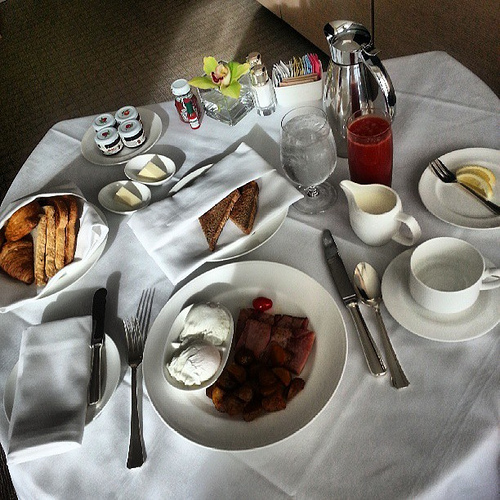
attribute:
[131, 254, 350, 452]
plate — white, round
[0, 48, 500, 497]
table — covered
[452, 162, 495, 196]
lemons — cut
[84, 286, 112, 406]
knife — silver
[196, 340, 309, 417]
potatoes — hashbrowns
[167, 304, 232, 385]
eggs — poached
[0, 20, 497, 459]
meal — fancy, breakfast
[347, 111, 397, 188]
glass — tall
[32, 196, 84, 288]
toast — sliced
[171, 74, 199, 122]
bottle — small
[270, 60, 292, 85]
sugar — collected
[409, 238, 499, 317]
cup — empty, white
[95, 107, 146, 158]
jellies — individual, jarred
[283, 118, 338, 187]
water — iced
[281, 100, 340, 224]
glass — filled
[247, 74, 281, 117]
shaker — salt